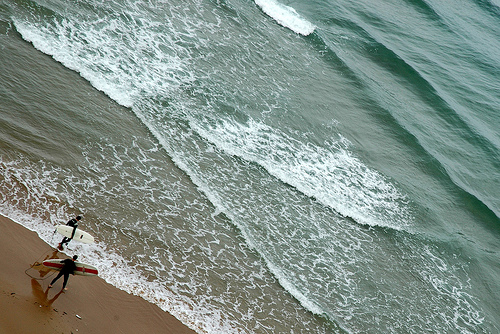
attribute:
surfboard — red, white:
[36, 243, 94, 284]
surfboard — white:
[30, 216, 99, 252]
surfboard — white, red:
[28, 256, 100, 277]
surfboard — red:
[26, 254, 100, 281]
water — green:
[312, 47, 472, 148]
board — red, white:
[24, 260, 40, 281]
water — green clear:
[326, 18, 495, 212]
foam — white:
[244, 131, 407, 231]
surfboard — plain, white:
[48, 216, 95, 246]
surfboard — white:
[51, 224, 97, 248]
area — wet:
[5, 219, 157, 324]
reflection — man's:
[25, 273, 62, 312]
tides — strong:
[334, 19, 484, 144]